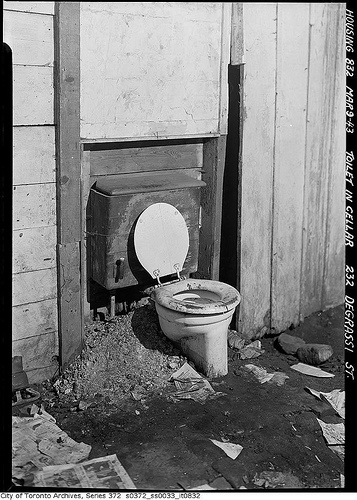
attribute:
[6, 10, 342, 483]
picture — black, white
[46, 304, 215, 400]
dirt — grey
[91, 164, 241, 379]
toilet — porcelain, dirty, old, grey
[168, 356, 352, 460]
papers — ripped, old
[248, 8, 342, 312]
wall — wooden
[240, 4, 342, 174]
wood — vertical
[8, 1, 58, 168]
boards — horizontal, wooden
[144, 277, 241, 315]
seat — dirty, worn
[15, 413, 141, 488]
newspaper — old, torn, wrinkled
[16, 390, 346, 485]
floor — dirty, dark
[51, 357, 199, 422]
rocks — black, white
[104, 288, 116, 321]
pipe — metal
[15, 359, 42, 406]
ice skate — old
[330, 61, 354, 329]
writing — white